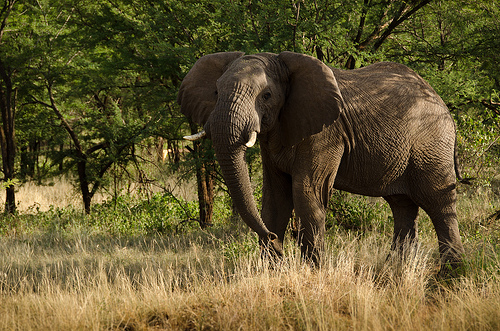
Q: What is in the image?
A: An elephant.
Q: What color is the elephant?
A: Gray.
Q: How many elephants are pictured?
A: One.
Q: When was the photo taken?
A: Daytime.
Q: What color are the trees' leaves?
A: Green.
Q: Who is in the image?
A: One elephant.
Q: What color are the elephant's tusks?
A: White.